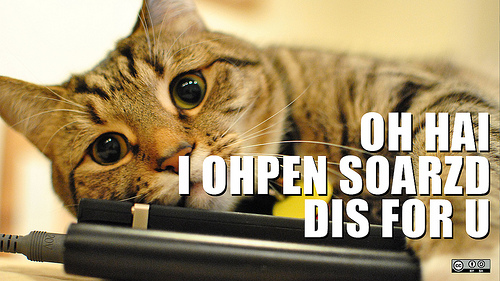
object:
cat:
[0, 0, 500, 281]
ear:
[0, 75, 64, 157]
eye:
[169, 67, 207, 109]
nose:
[147, 130, 195, 176]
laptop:
[75, 198, 407, 252]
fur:
[286, 82, 408, 145]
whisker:
[213, 82, 384, 201]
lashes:
[0, 108, 95, 131]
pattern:
[57, 37, 167, 126]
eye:
[85, 131, 134, 168]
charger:
[0, 222, 422, 281]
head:
[0, 0, 290, 218]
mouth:
[178, 179, 211, 207]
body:
[267, 44, 500, 281]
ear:
[133, 0, 211, 32]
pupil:
[176, 78, 206, 104]